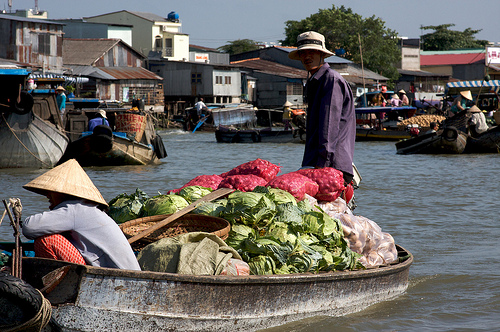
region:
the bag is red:
[276, 170, 318, 197]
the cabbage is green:
[235, 191, 275, 225]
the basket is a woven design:
[188, 215, 219, 235]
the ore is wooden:
[166, 178, 239, 203]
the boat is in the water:
[368, 258, 450, 315]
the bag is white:
[350, 223, 377, 246]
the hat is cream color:
[34, 145, 103, 212]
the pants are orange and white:
[49, 238, 75, 248]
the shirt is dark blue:
[317, 94, 344, 142]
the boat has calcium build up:
[208, 280, 298, 329]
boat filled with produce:
[5, 160, 410, 311]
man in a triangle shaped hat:
[15, 159, 142, 271]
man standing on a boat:
[291, 28, 357, 193]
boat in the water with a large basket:
[62, 104, 159, 164]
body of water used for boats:
[4, 131, 496, 328]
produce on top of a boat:
[108, 161, 398, 270]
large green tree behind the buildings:
[282, 10, 399, 75]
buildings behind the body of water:
[0, 8, 493, 111]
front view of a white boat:
[1, 114, 66, 162]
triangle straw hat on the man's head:
[22, 157, 109, 211]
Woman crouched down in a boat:
[5, 154, 143, 277]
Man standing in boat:
[290, 27, 361, 206]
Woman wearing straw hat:
[17, 152, 112, 210]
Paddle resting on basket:
[122, 189, 234, 245]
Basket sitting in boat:
[118, 210, 233, 262]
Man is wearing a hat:
[285, 27, 342, 59]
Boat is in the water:
[1, 157, 415, 330]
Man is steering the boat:
[290, 24, 365, 209]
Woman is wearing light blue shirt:
[15, 200, 143, 275]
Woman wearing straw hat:
[453, 85, 476, 102]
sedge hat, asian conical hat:
[18, 153, 113, 211]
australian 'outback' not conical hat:
[283, 26, 335, 65]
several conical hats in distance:
[273, 82, 478, 109]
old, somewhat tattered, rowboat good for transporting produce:
[1, 225, 433, 329]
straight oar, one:
[90, 175, 240, 257]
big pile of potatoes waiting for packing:
[393, 107, 449, 131]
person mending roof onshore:
[162, 6, 182, 26]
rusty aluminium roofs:
[63, 37, 170, 79]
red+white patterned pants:
[33, 229, 90, 269]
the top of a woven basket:
[116, 210, 233, 252]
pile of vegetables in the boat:
[100, 156, 395, 276]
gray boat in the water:
[11, 237, 436, 329]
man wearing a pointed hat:
[18, 158, 140, 270]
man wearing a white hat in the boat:
[287, 31, 353, 191]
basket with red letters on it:
[108, 109, 150, 140]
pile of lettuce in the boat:
[108, 186, 360, 278]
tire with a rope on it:
[0, 274, 53, 331]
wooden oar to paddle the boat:
[126, 187, 232, 248]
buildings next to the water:
[1, 1, 393, 120]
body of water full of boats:
[1, 121, 497, 331]